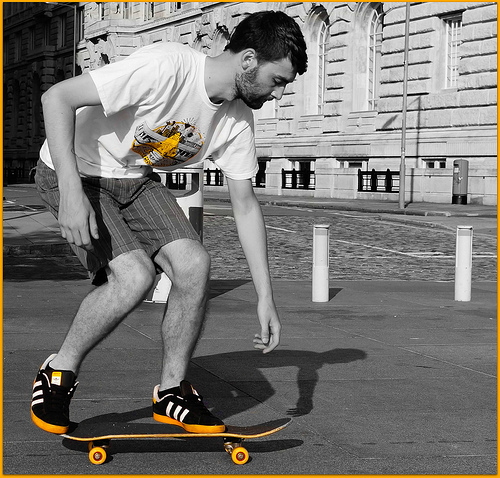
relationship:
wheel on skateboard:
[231, 445, 251, 468] [240, 417, 270, 436]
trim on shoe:
[152, 413, 224, 430] [152, 380, 227, 434]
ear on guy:
[232, 46, 261, 69] [31, 9, 310, 437]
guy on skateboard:
[31, 9, 310, 437] [43, 409, 301, 468]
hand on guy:
[57, 191, 100, 253] [31, 9, 310, 437]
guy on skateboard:
[31, 9, 310, 437] [61, 415, 294, 462]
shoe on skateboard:
[30, 352, 79, 435] [61, 415, 294, 462]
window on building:
[346, 2, 391, 116] [29, 4, 498, 221]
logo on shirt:
[126, 117, 197, 179] [44, 38, 256, 182]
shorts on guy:
[36, 159, 205, 269] [31, 9, 310, 437]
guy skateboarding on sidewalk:
[31, 9, 310, 437] [7, 276, 495, 473]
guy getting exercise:
[31, 9, 310, 437] [38, 2, 303, 459]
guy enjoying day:
[31, 9, 310, 437] [14, 7, 480, 460]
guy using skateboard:
[31, 9, 310, 437] [46, 403, 316, 475]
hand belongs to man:
[51, 191, 105, 251] [34, 30, 314, 415]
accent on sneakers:
[28, 366, 293, 466] [29, 351, 225, 433]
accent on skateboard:
[28, 366, 293, 466] [58, 415, 286, 467]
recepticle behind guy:
[132, 167, 206, 299] [31, 9, 310, 437]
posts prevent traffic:
[310, 222, 474, 304] [302, 200, 312, 207]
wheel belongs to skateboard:
[231, 446, 251, 467] [58, 415, 286, 467]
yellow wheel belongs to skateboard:
[88, 447, 107, 466] [58, 415, 286, 467]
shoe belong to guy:
[30, 352, 79, 435] [42, 22, 279, 400]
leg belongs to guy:
[152, 235, 209, 382] [31, 11, 307, 428]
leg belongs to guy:
[78, 258, 137, 336] [31, 11, 307, 428]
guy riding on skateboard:
[25, 9, 318, 457] [58, 414, 315, 466]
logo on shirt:
[131, 117, 205, 169] [59, 52, 259, 180]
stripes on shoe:
[165, 401, 189, 423] [152, 380, 227, 434]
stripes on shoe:
[29, 378, 42, 406] [152, 380, 227, 434]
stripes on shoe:
[165, 401, 189, 423] [30, 352, 79, 435]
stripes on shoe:
[29, 378, 42, 406] [30, 352, 79, 435]